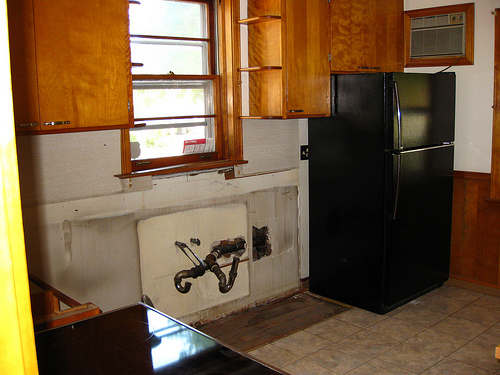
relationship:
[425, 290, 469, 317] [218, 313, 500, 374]
tile on floor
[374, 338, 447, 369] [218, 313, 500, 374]
tile on floor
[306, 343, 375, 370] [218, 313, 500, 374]
tile on floor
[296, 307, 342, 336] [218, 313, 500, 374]
tile on floor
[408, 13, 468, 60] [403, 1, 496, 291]
a.c. unit on wall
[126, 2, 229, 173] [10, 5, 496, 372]
window in kitchen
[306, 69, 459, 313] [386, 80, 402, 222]
refrigerator has handles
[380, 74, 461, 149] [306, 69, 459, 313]
freezer on top refrigerator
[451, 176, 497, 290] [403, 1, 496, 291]
wood on wall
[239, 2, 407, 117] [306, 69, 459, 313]
cabinets above refrigerator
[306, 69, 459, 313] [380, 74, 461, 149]
refrigerator has freezer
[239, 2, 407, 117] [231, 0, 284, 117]
cabinets has shelves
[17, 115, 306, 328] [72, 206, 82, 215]
wall has black spot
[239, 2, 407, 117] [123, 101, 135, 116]
cabinets has bracket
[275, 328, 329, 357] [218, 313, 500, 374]
tile on floor